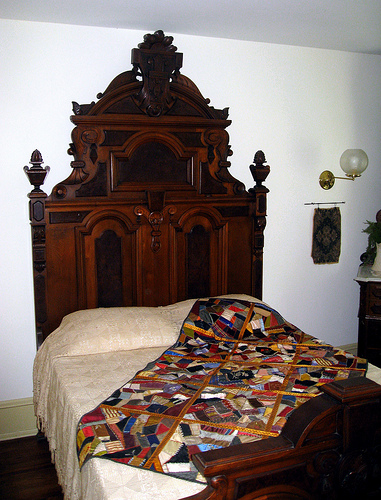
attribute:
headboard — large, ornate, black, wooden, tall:
[23, 29, 270, 351]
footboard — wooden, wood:
[178, 375, 381, 500]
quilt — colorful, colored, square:
[76, 296, 369, 485]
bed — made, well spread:
[23, 29, 381, 500]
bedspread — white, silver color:
[32, 292, 381, 500]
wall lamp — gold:
[319, 147, 370, 189]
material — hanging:
[310, 206, 342, 265]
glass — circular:
[339, 149, 368, 176]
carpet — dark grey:
[0, 435, 64, 499]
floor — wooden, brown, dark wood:
[0, 434, 66, 499]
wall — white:
[1, 19, 380, 441]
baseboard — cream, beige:
[0, 397, 40, 442]